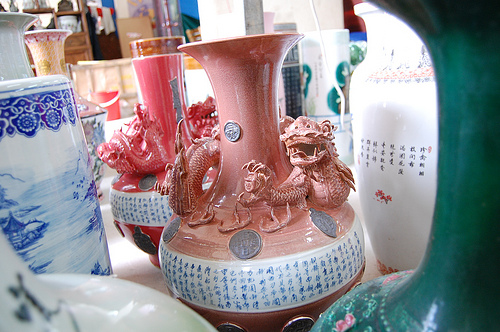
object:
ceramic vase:
[156, 32, 365, 331]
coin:
[217, 321, 238, 331]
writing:
[350, 138, 427, 179]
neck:
[94, 52, 216, 171]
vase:
[105, 46, 217, 273]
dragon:
[154, 116, 356, 218]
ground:
[341, 165, 379, 288]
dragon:
[236, 115, 356, 210]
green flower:
[300, 62, 313, 100]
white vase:
[21, 28, 103, 197]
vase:
[309, 0, 498, 332]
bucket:
[90, 90, 122, 121]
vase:
[0, 11, 35, 81]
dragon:
[95, 96, 221, 176]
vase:
[0, 74, 109, 281]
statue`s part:
[238, 160, 275, 207]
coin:
[222, 120, 242, 143]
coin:
[310, 209, 341, 239]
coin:
[228, 228, 263, 260]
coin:
[160, 216, 183, 245]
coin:
[283, 316, 315, 331]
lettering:
[158, 211, 364, 314]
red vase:
[95, 54, 221, 269]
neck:
[173, 31, 310, 201]